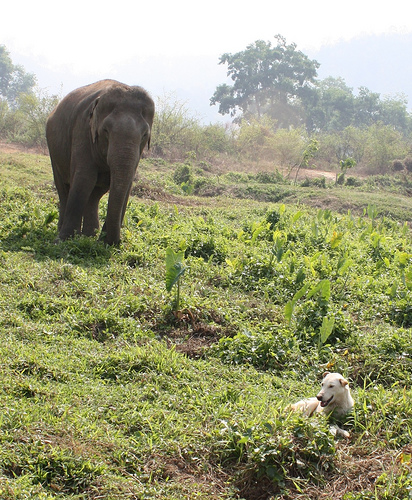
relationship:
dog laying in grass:
[285, 372, 354, 437] [0, 234, 404, 470]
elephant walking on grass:
[46, 79, 155, 249] [140, 388, 196, 438]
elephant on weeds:
[27, 79, 175, 240] [3, 173, 229, 311]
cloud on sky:
[0, 0, 411, 50] [3, 9, 407, 65]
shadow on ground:
[6, 233, 106, 263] [38, 269, 138, 326]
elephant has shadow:
[46, 79, 155, 249] [6, 233, 106, 263]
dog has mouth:
[283, 367, 357, 417] [313, 387, 334, 409]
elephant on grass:
[46, 79, 155, 249] [0, 150, 410, 497]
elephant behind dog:
[46, 79, 155, 249] [287, 361, 367, 441]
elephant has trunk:
[46, 79, 155, 249] [105, 136, 128, 226]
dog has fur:
[285, 372, 354, 437] [300, 397, 317, 412]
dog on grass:
[285, 372, 354, 437] [10, 172, 404, 451]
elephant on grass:
[46, 79, 155, 249] [10, 172, 404, 451]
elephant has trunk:
[46, 79, 155, 249] [103, 141, 141, 248]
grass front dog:
[224, 428, 335, 495] [295, 374, 353, 429]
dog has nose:
[285, 372, 354, 437] [314, 392, 329, 404]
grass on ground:
[0, 156, 412, 500] [58, 232, 122, 283]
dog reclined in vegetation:
[285, 372, 354, 437] [204, 204, 409, 368]